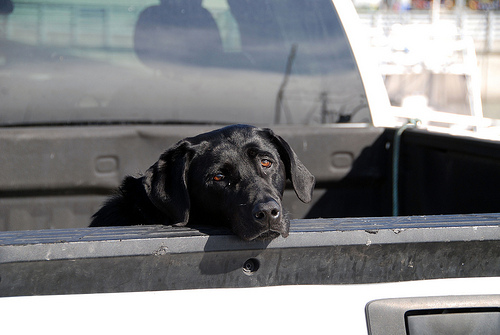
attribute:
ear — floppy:
[144, 141, 191, 228]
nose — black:
[248, 197, 280, 228]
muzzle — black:
[245, 200, 292, 242]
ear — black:
[148, 145, 198, 223]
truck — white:
[4, 3, 496, 293]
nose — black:
[249, 199, 284, 227]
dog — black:
[133, 97, 323, 274]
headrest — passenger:
[128, 7, 234, 57]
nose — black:
[254, 196, 283, 223]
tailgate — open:
[4, 209, 497, 331]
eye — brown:
[255, 148, 276, 178]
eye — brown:
[204, 170, 227, 190]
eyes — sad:
[209, 153, 279, 181]